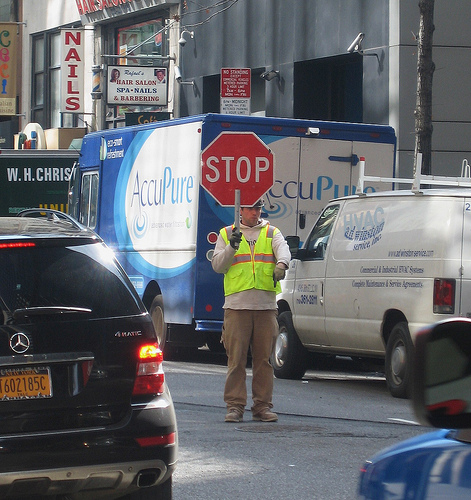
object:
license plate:
[0, 365, 53, 404]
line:
[386, 417, 422, 426]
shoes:
[251, 406, 279, 422]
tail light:
[432, 276, 457, 316]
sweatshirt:
[211, 216, 292, 310]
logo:
[129, 166, 193, 209]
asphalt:
[159, 353, 442, 500]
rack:
[354, 152, 471, 195]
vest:
[217, 220, 283, 298]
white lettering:
[205, 156, 271, 184]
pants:
[219, 309, 280, 418]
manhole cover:
[233, 421, 331, 435]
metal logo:
[9, 331, 30, 355]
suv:
[0, 206, 178, 500]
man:
[211, 195, 291, 422]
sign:
[200, 131, 276, 209]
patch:
[287, 463, 295, 468]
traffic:
[0, 112, 471, 500]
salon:
[20, 0, 182, 150]